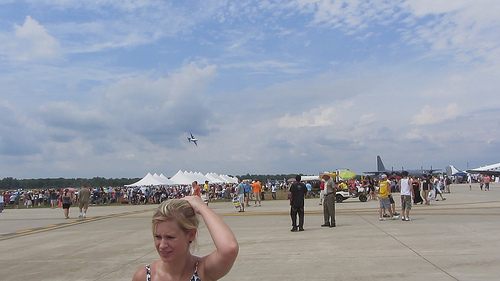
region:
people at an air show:
[1, 100, 497, 263]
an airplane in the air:
[182, 130, 200, 146]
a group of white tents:
[125, 165, 235, 185]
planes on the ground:
[365, 150, 499, 180]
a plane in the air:
[181, 126, 201, 147]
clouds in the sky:
[44, 28, 444, 174]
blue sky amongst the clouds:
[59, 12, 411, 107]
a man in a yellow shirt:
[377, 179, 390, 199]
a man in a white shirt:
[399, 178, 411, 193]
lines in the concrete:
[445, 194, 499, 227]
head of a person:
[142, 203, 204, 257]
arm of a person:
[192, 202, 242, 249]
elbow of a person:
[216, 239, 243, 257]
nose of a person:
[150, 242, 175, 257]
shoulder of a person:
[127, 251, 164, 275]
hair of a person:
[146, 198, 190, 222]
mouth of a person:
[153, 248, 175, 260]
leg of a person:
[282, 209, 316, 234]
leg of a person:
[316, 206, 346, 227]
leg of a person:
[396, 201, 417, 226]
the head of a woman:
[150, 207, 217, 257]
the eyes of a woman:
[138, 230, 205, 263]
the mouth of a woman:
[154, 244, 188, 265]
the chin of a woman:
[144, 239, 194, 265]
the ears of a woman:
[178, 224, 200, 246]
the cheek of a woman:
[165, 231, 199, 260]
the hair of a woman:
[136, 179, 214, 248]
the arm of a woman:
[186, 191, 283, 273]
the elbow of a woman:
[196, 224, 249, 271]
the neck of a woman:
[148, 215, 229, 273]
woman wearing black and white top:
[121, 174, 258, 272]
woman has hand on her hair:
[117, 176, 247, 273]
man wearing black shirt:
[275, 163, 311, 238]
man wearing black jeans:
[270, 163, 309, 243]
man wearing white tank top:
[395, 163, 418, 228]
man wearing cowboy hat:
[312, 164, 345, 236]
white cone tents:
[128, 164, 245, 194]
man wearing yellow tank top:
[368, 170, 395, 220]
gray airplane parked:
[362, 154, 449, 180]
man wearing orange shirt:
[247, 178, 268, 204]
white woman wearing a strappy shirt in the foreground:
[130, 191, 223, 279]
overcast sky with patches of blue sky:
[2, 2, 494, 167]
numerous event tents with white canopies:
[121, 167, 243, 202]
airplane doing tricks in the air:
[183, 129, 203, 149]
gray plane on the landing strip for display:
[364, 153, 444, 184]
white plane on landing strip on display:
[442, 158, 498, 183]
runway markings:
[0, 199, 146, 239]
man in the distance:
[285, 168, 311, 233]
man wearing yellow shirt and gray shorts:
[372, 170, 396, 218]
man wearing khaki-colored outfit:
[75, 180, 95, 217]